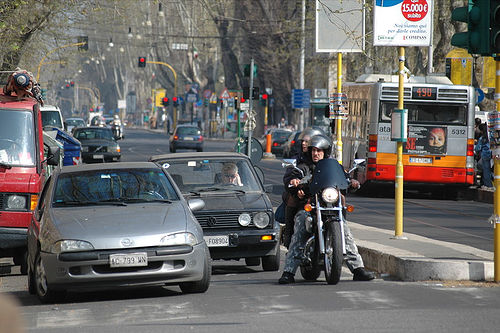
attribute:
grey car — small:
[26, 155, 218, 299]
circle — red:
[44, 57, 84, 95]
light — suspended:
[260, 90, 270, 110]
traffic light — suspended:
[134, 56, 149, 68]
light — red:
[139, 54, 154, 70]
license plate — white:
[107, 246, 150, 269]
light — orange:
[342, 202, 357, 217]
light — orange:
[300, 193, 316, 215]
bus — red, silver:
[330, 73, 476, 201]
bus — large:
[343, 74, 475, 197]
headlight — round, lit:
[314, 186, 341, 207]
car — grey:
[27, 162, 213, 302]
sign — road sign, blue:
[289, 86, 316, 111]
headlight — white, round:
[320, 184, 340, 204]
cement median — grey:
[351, 220, 498, 284]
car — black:
[145, 146, 295, 290]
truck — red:
[0, 71, 57, 243]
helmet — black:
[305, 132, 332, 155]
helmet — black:
[296, 124, 328, 135]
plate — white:
[198, 217, 246, 252]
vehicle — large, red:
[1, 68, 46, 272]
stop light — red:
[170, 93, 185, 105]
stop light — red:
[159, 95, 172, 108]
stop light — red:
[137, 57, 149, 66]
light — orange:
[303, 201, 314, 214]